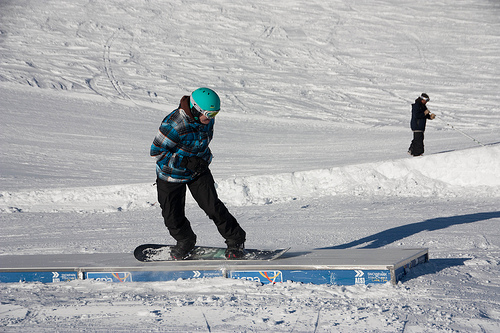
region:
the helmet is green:
[165, 75, 227, 137]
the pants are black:
[128, 153, 253, 270]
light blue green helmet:
[189, 86, 221, 113]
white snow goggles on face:
[201, 111, 218, 118]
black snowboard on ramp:
[133, 242, 288, 263]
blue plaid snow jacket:
[154, 113, 209, 179]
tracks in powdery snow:
[86, 76, 94, 94]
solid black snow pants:
[156, 179, 231, 246]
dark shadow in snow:
[369, 224, 419, 244]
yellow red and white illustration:
[257, 271, 284, 283]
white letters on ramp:
[353, 276, 368, 285]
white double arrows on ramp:
[190, 269, 202, 276]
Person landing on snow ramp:
[131, 83, 293, 262]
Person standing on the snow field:
[407, 91, 437, 161]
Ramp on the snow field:
[0, 245, 431, 285]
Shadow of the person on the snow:
[312, 210, 499, 250]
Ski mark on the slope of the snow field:
[97, 24, 139, 103]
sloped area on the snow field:
[2, 2, 499, 132]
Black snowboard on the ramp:
[131, 241, 290, 263]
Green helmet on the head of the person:
[187, 85, 223, 115]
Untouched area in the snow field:
[0, 107, 150, 162]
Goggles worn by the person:
[202, 108, 219, 118]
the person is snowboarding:
[94, 74, 294, 289]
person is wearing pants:
[153, 173, 274, 285]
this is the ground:
[237, 9, 361, 109]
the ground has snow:
[241, 144, 280, 168]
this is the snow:
[304, 201, 368, 232]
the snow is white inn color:
[321, 201, 378, 239]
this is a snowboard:
[133, 244, 293, 264]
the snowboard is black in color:
[136, 248, 145, 258]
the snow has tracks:
[168, 10, 258, 45]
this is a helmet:
[194, 89, 211, 104]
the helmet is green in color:
[197, 92, 210, 100]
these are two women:
[152, 75, 437, 249]